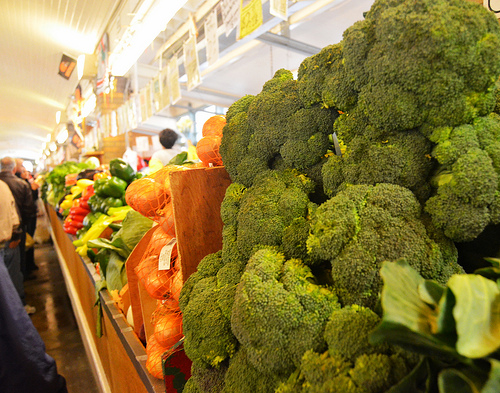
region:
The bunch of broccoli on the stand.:
[191, 3, 456, 390]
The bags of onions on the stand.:
[123, 91, 234, 385]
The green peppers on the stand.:
[85, 153, 140, 218]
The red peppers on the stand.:
[67, 185, 98, 235]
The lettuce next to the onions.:
[102, 214, 139, 291]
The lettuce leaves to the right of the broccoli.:
[370, 229, 497, 391]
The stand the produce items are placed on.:
[28, 183, 183, 389]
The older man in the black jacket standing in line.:
[3, 149, 37, 236]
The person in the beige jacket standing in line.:
[0, 179, 27, 244]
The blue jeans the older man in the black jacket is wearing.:
[10, 240, 37, 301]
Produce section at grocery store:
[43, 19, 433, 363]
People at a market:
[0, 153, 68, 255]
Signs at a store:
[58, 34, 223, 118]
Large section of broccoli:
[241, 87, 489, 380]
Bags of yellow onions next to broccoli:
[130, 152, 267, 362]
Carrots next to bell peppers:
[61, 168, 136, 237]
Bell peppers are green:
[85, 162, 122, 211]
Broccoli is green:
[296, 83, 425, 349]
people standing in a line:
[0, 125, 57, 265]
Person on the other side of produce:
[133, 117, 183, 159]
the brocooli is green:
[243, 90, 476, 389]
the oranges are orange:
[128, 175, 189, 331]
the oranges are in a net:
[132, 190, 191, 327]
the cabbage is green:
[128, 210, 144, 252]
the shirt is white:
[156, 148, 182, 162]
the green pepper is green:
[82, 157, 131, 213]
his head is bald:
[3, 147, 17, 179]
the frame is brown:
[160, 165, 227, 247]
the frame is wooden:
[167, 164, 227, 261]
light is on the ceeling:
[43, 20, 124, 61]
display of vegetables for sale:
[34, 4, 499, 391]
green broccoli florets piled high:
[158, 2, 498, 389]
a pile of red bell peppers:
[57, 180, 94, 236]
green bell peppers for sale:
[70, 154, 136, 261]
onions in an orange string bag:
[109, 109, 251, 384]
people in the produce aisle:
[2, 152, 90, 392]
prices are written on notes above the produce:
[57, 3, 304, 146]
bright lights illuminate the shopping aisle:
[27, 4, 217, 170]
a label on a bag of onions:
[155, 231, 179, 273]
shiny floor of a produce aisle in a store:
[26, 225, 85, 389]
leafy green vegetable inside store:
[364, 259, 499, 364]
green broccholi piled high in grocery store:
[178, 0, 499, 391]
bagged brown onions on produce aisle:
[123, 115, 226, 380]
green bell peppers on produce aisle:
[81, 156, 146, 247]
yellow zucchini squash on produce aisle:
[71, 205, 130, 258]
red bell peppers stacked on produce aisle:
[61, 183, 96, 235]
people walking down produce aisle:
[0, 154, 112, 391]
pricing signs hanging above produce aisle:
[35, 0, 303, 169]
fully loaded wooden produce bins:
[39, 157, 233, 392]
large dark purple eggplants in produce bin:
[54, 166, 103, 220]